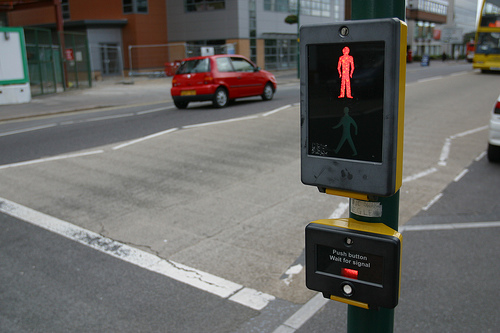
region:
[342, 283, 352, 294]
the button is white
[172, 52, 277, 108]
the car is red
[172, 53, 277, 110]
the car is compact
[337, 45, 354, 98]
the image of the standing person is red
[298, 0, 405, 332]
the digital crosswalk signals on the pole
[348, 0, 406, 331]
the pole is green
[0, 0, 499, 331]
the buildings along the wide street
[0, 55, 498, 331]
the red car on the wide street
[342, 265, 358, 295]
the red light above the white button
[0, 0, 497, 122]
the sidewalk in front of the buildings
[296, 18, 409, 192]
a gray and yellow pedestrian box signal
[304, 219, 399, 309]
a red button on a black and yellow box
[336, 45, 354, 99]
red lit picture of a man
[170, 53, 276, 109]
red car with a yellow license plate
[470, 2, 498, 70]
a yellow double decker bus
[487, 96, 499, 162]
a white car with red taillight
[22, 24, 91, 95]
a red sign on a green metal fence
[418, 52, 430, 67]
a blue and white sign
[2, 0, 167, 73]
a brick building with dark windows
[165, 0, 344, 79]
a gray building with glass windows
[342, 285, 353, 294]
white button one who wished to cross would push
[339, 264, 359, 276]
rectangular red button on sign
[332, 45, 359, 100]
lit red pedestrian on sign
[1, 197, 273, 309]
white line on the pavement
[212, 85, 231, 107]
right rear tire of the red car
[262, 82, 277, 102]
right front tire of the red car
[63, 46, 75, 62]
red sign on the fence across the street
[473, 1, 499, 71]
yellow bus on the road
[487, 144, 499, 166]
tire of the white vehicle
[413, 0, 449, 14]
row of windows in a building across the street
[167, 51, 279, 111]
Small red car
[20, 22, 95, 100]
tall green gate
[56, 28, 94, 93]
Red sign on green gate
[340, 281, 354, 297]
Button a machine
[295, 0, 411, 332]
Green post with pedestrian warning device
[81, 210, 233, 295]
cracked on the road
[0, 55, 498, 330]
Road is made of asphalt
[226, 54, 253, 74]
Car window that is not fully closed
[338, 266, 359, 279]
red light on a machine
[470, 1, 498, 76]
Partially seen double decker bus